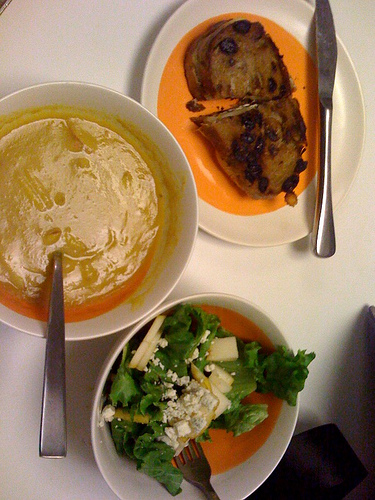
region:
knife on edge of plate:
[302, 1, 341, 257]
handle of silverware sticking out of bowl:
[29, 253, 75, 452]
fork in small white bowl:
[174, 441, 224, 499]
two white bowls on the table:
[3, 80, 309, 498]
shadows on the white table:
[13, 307, 374, 488]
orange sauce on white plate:
[154, 20, 332, 216]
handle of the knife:
[312, 110, 338, 256]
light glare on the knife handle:
[313, 108, 338, 254]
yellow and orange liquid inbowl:
[7, 118, 158, 313]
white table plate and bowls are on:
[5, 4, 374, 486]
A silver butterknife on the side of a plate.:
[313, 1, 337, 257]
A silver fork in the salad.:
[171, 436, 222, 498]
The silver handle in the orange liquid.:
[39, 251, 68, 459]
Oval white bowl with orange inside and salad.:
[91, 292, 299, 498]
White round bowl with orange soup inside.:
[0, 79, 199, 342]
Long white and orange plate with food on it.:
[138, 0, 368, 246]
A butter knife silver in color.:
[307, 0, 339, 256]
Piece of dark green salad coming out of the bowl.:
[243, 338, 316, 406]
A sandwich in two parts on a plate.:
[184, 18, 306, 198]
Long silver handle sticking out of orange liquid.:
[37, 250, 69, 457]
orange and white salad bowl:
[99, 301, 283, 473]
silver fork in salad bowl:
[168, 435, 217, 495]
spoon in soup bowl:
[36, 245, 66, 455]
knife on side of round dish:
[303, 0, 336, 261]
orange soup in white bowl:
[0, 101, 189, 319]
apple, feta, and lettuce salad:
[92, 301, 312, 487]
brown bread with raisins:
[180, 15, 304, 196]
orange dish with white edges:
[141, 0, 366, 247]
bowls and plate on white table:
[0, 0, 374, 498]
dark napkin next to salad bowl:
[251, 416, 369, 497]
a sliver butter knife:
[311, 4, 352, 256]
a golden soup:
[37, 137, 127, 237]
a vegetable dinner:
[105, 311, 310, 499]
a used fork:
[175, 457, 235, 497]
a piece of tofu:
[131, 315, 164, 372]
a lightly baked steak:
[191, 25, 310, 98]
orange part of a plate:
[159, 70, 193, 126]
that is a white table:
[30, 8, 121, 68]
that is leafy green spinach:
[250, 346, 304, 391]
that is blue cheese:
[161, 388, 195, 430]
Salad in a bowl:
[102, 309, 285, 490]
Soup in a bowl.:
[23, 164, 149, 297]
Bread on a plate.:
[192, 14, 309, 196]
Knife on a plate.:
[306, 6, 337, 261]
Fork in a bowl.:
[166, 427, 222, 499]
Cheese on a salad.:
[165, 368, 218, 454]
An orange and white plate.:
[150, 1, 359, 262]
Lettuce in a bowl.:
[152, 332, 217, 398]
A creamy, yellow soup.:
[19, 143, 122, 276]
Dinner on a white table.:
[10, 1, 372, 497]